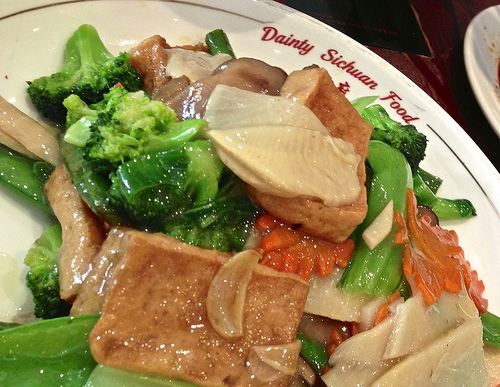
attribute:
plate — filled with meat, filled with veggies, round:
[1, 4, 498, 383]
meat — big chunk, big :
[91, 222, 319, 382]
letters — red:
[262, 32, 437, 147]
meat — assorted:
[9, 21, 461, 381]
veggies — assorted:
[14, 25, 476, 380]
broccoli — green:
[60, 28, 120, 90]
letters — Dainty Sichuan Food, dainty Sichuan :
[259, 22, 421, 124]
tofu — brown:
[89, 235, 323, 383]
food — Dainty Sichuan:
[28, 39, 452, 383]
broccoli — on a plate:
[32, 39, 221, 232]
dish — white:
[365, 40, 439, 122]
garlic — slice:
[203, 236, 260, 349]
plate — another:
[450, 15, 499, 107]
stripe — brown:
[1, 3, 496, 234]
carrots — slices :
[377, 186, 492, 298]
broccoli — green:
[22, 17, 144, 120]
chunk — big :
[93, 220, 302, 381]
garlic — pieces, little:
[202, 247, 260, 339]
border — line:
[219, 8, 494, 218]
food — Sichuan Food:
[378, 85, 415, 127]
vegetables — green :
[39, 37, 413, 287]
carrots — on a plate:
[253, 201, 494, 301]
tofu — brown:
[244, 63, 373, 245]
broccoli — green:
[57, 87, 207, 164]